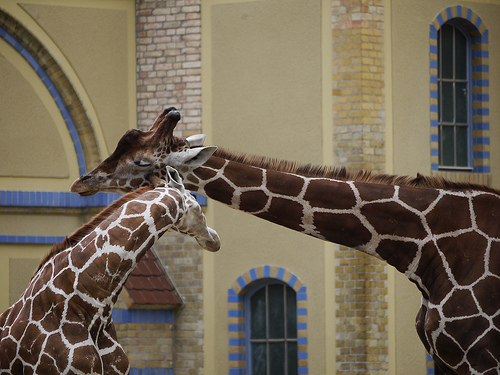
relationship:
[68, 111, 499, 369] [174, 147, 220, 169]
giraffe has ear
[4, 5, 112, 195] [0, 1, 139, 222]
arch in window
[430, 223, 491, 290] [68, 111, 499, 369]
spot on giraffe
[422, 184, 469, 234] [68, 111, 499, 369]
spot on giraffe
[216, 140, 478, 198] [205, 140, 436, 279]
hair along neck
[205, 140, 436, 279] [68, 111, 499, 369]
neck of giraffe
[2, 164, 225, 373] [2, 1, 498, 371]
giraffe in front of a building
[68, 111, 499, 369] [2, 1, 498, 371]
giraffe in front of a building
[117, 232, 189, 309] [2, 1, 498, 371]
shingles on part of building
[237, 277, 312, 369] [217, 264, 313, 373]
window with border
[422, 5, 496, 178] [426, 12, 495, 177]
window with border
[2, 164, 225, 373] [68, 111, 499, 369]
giraffe showing affection to giraffe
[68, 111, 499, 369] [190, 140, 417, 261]
giraffe with neck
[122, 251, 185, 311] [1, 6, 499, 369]
tile on wall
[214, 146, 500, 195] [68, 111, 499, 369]
hair on giraffe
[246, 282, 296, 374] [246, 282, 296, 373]
bars on window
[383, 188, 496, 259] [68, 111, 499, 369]
spots on giraffe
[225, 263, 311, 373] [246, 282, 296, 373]
frame around window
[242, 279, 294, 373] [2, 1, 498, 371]
window on building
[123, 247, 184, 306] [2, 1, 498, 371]
shingles on building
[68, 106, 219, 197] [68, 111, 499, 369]
giraffe's head of giraffe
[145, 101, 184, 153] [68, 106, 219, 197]
horns on giraffe's head